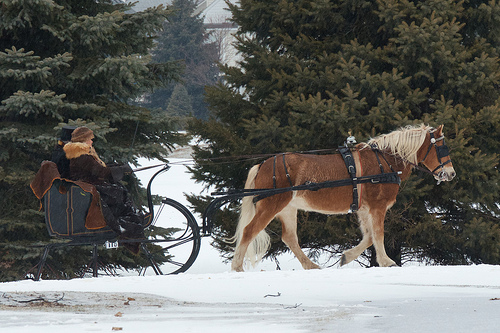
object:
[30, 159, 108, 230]
fabric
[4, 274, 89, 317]
twig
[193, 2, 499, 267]
tree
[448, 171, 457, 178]
nose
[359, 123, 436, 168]
mane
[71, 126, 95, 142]
cap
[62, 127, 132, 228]
lady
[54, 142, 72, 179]
coat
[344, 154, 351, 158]
metal buckles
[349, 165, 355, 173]
metal buckles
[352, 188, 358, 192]
metal buckles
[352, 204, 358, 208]
metal buckles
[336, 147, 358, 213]
black harnass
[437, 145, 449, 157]
horse eye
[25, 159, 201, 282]
carriage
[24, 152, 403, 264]
sleigh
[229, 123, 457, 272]
brown horse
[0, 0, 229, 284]
tree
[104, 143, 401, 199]
reigns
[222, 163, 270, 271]
tail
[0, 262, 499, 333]
white snow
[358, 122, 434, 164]
long hair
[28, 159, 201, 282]
cart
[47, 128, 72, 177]
passenger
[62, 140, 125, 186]
coat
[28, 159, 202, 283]
sled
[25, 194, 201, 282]
gliders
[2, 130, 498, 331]
ground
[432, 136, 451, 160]
flap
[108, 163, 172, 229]
rope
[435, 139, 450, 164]
blinder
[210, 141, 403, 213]
harness